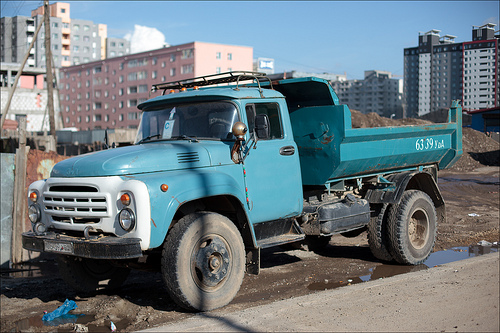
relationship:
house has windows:
[52, 36, 262, 132] [62, 71, 84, 122]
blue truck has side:
[22, 70, 463, 313] [125, 145, 445, 235]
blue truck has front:
[22, 70, 463, 313] [33, 140, 171, 281]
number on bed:
[415, 138, 421, 151] [289, 83, 463, 173]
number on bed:
[415, 138, 445, 151] [289, 83, 463, 173]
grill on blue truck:
[43, 182, 112, 235] [22, 70, 463, 313]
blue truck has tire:
[22, 70, 463, 313] [166, 212, 251, 312]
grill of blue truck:
[37, 179, 112, 235] [22, 70, 463, 313]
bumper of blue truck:
[21, 228, 143, 259] [22, 70, 463, 313]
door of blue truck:
[239, 93, 303, 224] [22, 70, 463, 313]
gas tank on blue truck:
[297, 191, 374, 238] [22, 71, 467, 316]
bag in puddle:
[38, 297, 79, 323] [1, 298, 138, 331]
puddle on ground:
[1, 298, 138, 331] [0, 170, 499, 331]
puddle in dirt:
[342, 242, 499, 284] [4, 105, 499, 331]